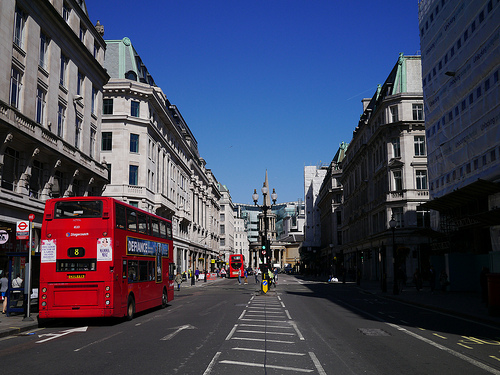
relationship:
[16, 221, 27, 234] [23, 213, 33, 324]
sign in pole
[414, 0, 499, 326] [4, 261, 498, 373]
building in road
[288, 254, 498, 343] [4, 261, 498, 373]
shade in road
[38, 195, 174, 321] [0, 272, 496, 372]
bus in street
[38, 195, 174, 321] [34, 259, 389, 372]
bus in road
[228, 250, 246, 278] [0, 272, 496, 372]
bus in street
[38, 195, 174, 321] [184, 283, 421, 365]
bus on road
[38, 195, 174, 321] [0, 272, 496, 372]
bus on street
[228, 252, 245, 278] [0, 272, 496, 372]
bus on street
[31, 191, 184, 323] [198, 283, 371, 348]
bus on road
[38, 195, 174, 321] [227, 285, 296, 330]
bus on street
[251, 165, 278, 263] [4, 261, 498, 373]
lamp on road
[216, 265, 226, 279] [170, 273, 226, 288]
sign on sidewalk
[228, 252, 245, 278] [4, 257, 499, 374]
bus further down street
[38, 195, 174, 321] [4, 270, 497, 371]
bus on road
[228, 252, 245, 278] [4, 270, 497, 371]
bus on road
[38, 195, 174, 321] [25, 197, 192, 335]
bus behind bus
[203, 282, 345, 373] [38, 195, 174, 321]
street for bus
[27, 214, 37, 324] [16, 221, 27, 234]
pole with sign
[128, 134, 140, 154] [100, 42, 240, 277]
window of buildings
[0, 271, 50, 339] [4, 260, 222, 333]
human on sidewalk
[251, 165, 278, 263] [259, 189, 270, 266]
lamp on pole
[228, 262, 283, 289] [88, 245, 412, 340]
people crossing street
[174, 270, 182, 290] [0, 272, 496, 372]
person crossing street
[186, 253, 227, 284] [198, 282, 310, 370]
people walking on street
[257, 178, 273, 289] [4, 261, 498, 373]
lamp in middle of road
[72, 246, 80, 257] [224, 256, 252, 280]
number on back of bus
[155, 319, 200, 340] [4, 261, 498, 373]
arrow in road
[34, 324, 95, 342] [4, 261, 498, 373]
arrow in road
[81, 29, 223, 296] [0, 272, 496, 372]
building on side of street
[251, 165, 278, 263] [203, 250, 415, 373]
lamp on street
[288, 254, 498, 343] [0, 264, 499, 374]
shade on ground